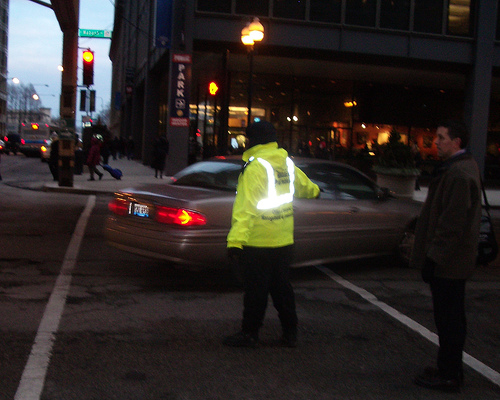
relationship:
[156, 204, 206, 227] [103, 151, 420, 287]
light on back of car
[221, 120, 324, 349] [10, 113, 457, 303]
man directing traffic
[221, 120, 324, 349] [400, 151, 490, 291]
man wearing a coat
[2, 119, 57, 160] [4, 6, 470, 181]
traffic moving through city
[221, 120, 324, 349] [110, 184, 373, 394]
man in crosswalk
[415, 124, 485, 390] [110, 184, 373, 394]
pedestrian in crosswalk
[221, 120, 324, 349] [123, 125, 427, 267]
man directing traffic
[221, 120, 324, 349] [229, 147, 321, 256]
man wearing coat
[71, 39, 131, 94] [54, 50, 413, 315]
traffic light operating in city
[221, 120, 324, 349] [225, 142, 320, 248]
man has coat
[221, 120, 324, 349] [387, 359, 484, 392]
man standing by curb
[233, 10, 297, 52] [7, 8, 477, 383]
light in area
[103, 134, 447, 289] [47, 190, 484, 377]
car on street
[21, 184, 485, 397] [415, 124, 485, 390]
crosswalk for pedestrian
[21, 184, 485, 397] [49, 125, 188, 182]
crosswalk for pedestrians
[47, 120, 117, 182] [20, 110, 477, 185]
people in background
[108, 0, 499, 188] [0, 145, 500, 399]
business near street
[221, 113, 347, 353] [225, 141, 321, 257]
man in coat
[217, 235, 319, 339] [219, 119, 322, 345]
pant in man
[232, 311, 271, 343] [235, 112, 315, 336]
foot of man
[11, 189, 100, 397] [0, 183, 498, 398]
line on street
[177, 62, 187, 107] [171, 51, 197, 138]
word on pole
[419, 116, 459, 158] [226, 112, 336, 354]
head of man